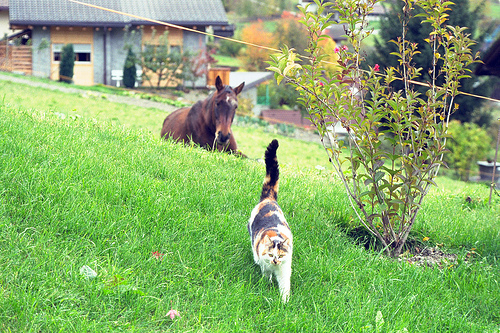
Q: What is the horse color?
A: Brown.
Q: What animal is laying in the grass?
A: Horse.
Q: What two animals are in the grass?
A: Cat and a horse.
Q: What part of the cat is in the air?
A: The tail.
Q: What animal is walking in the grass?
A: Cat.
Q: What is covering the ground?
A: Grass.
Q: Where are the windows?
A: On the yellow and grey house.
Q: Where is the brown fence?
A: Behind the house.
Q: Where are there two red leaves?
A: In the grass.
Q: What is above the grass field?
A: A yellow string.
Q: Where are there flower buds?
A: On a bush.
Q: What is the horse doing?
A: Laying in the grass.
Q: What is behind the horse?
A: A small building.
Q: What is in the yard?
A: A small bush.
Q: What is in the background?
A: Tall blurry trees.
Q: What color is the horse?
A: Brown.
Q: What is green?
A: The grass.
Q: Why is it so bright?
A: Sunny.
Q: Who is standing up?
A: The cat.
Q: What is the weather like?
A: Clear skies.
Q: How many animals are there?
A: Two.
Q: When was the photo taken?
A: Day time.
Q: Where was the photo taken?
A: Near horse.